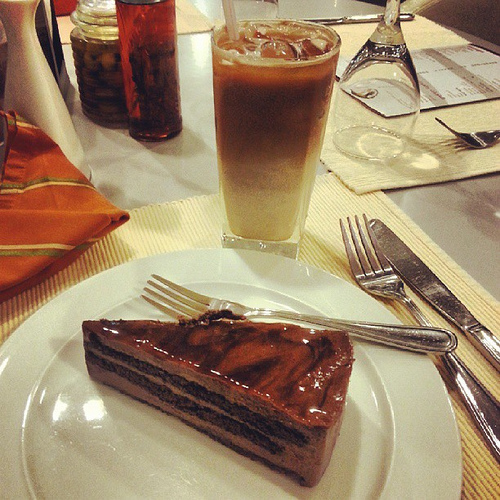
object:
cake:
[82, 309, 353, 489]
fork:
[339, 213, 500, 465]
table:
[1, 1, 498, 500]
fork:
[433, 115, 500, 150]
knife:
[369, 217, 500, 371]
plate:
[1, 249, 463, 500]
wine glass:
[333, 0, 419, 161]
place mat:
[1, 171, 500, 498]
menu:
[336, 42, 500, 117]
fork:
[142, 273, 460, 354]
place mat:
[322, 13, 500, 197]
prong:
[147, 279, 207, 311]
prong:
[143, 287, 201, 317]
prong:
[141, 294, 191, 321]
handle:
[254, 308, 459, 355]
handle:
[402, 292, 500, 463]